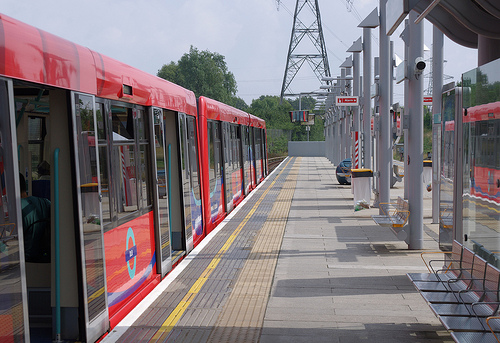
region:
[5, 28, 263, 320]
train on the track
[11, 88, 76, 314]
door on train that is open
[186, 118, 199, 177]
window on a train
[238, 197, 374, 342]
platform of the train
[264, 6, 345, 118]
tower at end of platform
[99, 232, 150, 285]
graphic on the train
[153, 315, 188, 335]
thick yellow strip on platform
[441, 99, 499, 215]
reflection of the train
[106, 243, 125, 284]
color of red on train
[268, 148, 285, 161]
track train is on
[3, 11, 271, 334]
shiny red commuter train in Britain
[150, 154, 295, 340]
yellow line on gray platform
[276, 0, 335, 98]
large power scaffolding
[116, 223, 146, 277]
turquoise and navy circle logo of train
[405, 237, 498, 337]
hard metal red and silver waiting seats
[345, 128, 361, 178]
red and white traffic pole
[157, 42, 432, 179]
green trees in background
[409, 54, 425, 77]
small white surveilience camera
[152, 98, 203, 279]
sliding doors of train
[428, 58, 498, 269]
train schedule displays behind seats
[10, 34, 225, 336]
red train at platform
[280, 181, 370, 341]
grey concrete on platform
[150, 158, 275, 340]
yellow line on platform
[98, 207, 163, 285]
blue logo on train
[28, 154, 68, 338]
green pole in train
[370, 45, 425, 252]
grey poles near platform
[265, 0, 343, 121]
tall grey power pole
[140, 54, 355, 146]
green trees in distance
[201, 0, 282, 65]
sky is grey and overcast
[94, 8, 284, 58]
thick clouds in sky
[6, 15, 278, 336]
this is a train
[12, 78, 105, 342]
this is a sign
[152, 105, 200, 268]
this is a sign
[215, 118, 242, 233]
this is a sign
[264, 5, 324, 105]
this is a mast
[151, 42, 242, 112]
this is a tree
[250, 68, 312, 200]
this is a tree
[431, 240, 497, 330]
this is a bench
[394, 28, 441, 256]
this is made of metal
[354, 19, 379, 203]
this is made of metal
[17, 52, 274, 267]
red train cars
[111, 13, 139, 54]
white clouds in blue sky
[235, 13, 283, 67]
white clouds in blue sky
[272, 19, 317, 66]
white clouds in blue sky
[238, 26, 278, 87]
white clouds in blue sky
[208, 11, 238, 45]
white clouds in blue sky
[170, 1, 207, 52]
white clouds in blue sky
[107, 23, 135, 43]
white clouds in blue sky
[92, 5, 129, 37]
white clouds in blue sky